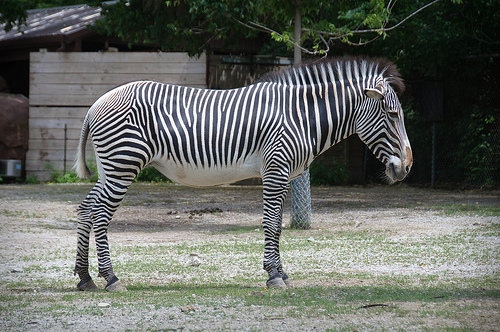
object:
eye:
[387, 110, 399, 119]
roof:
[0, 2, 112, 39]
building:
[0, 0, 294, 182]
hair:
[252, 54, 404, 95]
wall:
[30, 53, 97, 110]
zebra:
[70, 54, 413, 293]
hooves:
[77, 279, 100, 292]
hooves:
[104, 279, 129, 293]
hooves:
[283, 277, 294, 287]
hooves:
[266, 277, 287, 290]